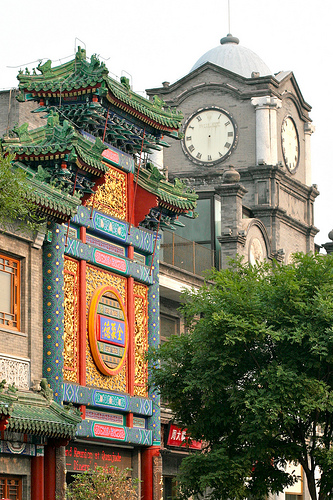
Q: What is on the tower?
A: Clocks.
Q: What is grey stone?
A: Tower.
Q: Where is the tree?
A: In the front.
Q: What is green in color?
A: Roof.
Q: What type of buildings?
A: Asian.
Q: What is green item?
A: Roofing.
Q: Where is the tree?
A: In foreground.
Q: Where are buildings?
A: On street.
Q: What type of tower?
A: Clock.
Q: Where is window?
A: Over roof.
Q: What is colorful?
A: Signage.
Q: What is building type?
A: Pagoda.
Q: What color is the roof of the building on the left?
A: Green.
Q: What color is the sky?
A: White.